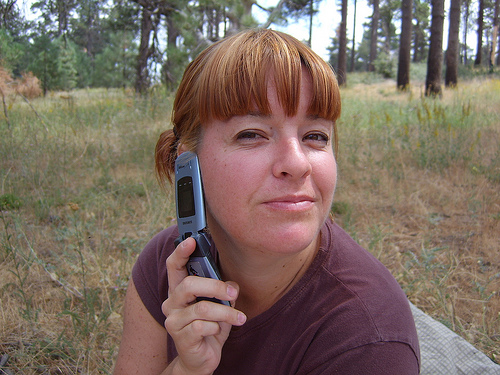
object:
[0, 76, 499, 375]
grass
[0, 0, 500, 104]
forest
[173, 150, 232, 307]
phone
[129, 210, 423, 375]
shirt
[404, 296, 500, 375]
bench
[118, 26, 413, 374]
girl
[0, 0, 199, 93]
leaves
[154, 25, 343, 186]
hair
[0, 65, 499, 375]
weeds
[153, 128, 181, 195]
ponytail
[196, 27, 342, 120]
bangs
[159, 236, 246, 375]
hand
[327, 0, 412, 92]
trees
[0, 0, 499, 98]
woods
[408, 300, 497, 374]
log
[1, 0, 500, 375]
park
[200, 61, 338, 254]
face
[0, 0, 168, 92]
tree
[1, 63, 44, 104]
bush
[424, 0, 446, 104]
tree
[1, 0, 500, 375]
landscape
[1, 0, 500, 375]
area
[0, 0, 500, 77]
sky